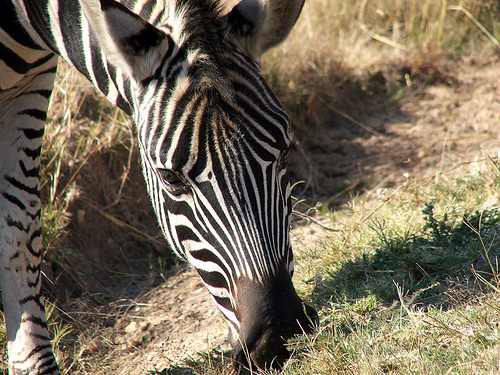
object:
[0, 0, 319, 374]
zebra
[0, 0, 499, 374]
field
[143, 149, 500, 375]
grass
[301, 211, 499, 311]
shadow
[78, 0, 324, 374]
head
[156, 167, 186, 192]
eye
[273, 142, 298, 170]
eye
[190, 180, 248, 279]
stripes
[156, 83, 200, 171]
stripes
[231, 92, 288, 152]
stripes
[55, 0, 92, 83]
stripes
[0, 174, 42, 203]
stripes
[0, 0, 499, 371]
ground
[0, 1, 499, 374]
grass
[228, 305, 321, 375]
nose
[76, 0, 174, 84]
ear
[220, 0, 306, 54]
ear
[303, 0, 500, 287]
sunshine